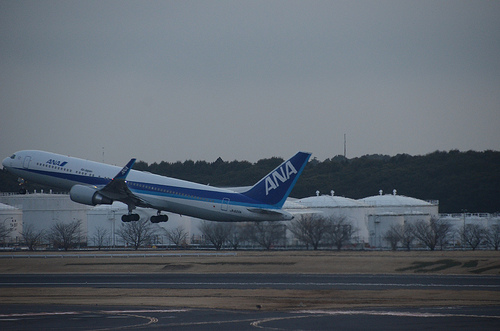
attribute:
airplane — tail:
[5, 131, 360, 267]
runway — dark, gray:
[3, 270, 498, 290]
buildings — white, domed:
[4, 184, 497, 255]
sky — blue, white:
[1, 1, 499, 166]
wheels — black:
[118, 211, 172, 226]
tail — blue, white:
[229, 145, 319, 232]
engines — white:
[66, 181, 138, 215]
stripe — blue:
[21, 161, 280, 210]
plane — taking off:
[0, 129, 285, 225]